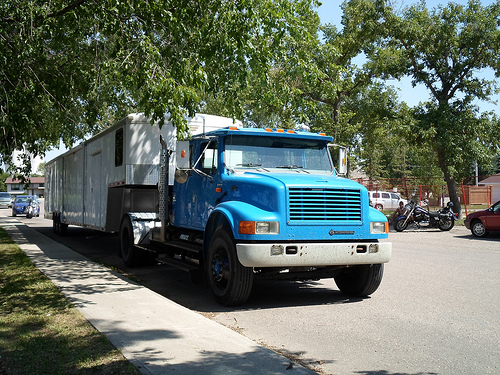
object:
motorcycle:
[393, 194, 459, 233]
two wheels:
[394, 216, 411, 233]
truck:
[40, 109, 394, 308]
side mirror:
[338, 147, 348, 174]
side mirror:
[175, 140, 191, 169]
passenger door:
[190, 139, 220, 229]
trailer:
[41, 113, 254, 234]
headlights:
[255, 218, 281, 235]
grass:
[0, 225, 132, 375]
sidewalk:
[0, 210, 320, 375]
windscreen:
[224, 134, 333, 173]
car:
[464, 200, 499, 238]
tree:
[322, 0, 499, 227]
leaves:
[448, 2, 498, 47]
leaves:
[93, 0, 205, 72]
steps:
[162, 238, 203, 253]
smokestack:
[156, 135, 174, 242]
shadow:
[0, 216, 453, 375]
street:
[0, 189, 498, 373]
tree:
[271, 21, 405, 228]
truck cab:
[172, 122, 397, 267]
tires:
[57, 214, 70, 235]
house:
[477, 174, 499, 205]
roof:
[476, 174, 499, 185]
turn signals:
[238, 221, 256, 235]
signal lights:
[369, 220, 388, 235]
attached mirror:
[173, 169, 188, 184]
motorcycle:
[26, 194, 42, 219]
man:
[388, 201, 409, 226]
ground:
[0, 203, 500, 375]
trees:
[334, 1, 499, 218]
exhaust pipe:
[157, 150, 170, 240]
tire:
[114, 215, 140, 265]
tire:
[329, 258, 386, 298]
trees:
[0, 0, 325, 161]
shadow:
[390, 228, 448, 233]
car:
[12, 194, 41, 219]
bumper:
[235, 241, 394, 268]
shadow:
[13, 221, 372, 312]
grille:
[284, 186, 362, 226]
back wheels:
[52, 216, 56, 233]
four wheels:
[199, 221, 258, 307]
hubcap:
[210, 251, 227, 282]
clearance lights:
[229, 125, 238, 130]